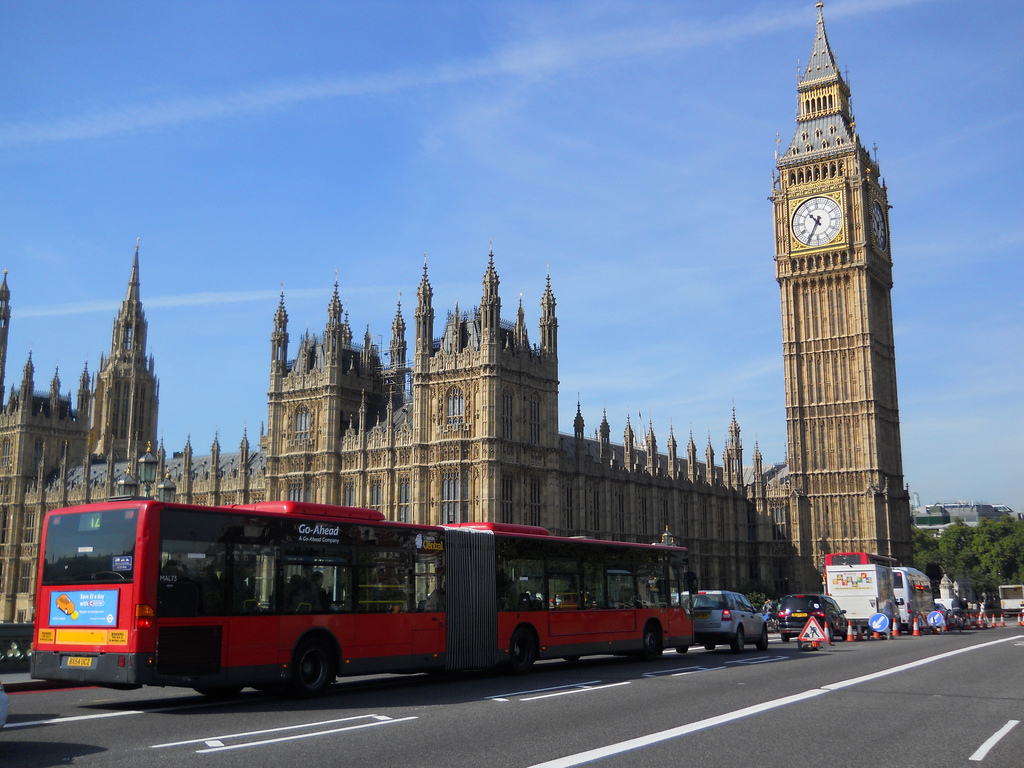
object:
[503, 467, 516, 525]
window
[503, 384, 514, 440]
window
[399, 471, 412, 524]
window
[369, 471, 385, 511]
window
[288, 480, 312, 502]
window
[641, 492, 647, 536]
window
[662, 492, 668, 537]
window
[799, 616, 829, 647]
sign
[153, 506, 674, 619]
window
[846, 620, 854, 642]
pylon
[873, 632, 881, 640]
pylon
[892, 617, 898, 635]
pylon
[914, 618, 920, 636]
pylon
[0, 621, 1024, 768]
road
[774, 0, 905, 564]
big ben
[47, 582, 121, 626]
advertising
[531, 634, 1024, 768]
line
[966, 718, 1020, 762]
line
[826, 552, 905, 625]
truck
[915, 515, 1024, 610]
tree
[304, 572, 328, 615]
passenger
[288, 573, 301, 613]
passenger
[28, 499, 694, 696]
bus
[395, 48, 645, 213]
white clouds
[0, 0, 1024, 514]
blue sky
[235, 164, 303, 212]
sky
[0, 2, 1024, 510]
clouds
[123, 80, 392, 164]
clouds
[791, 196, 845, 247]
clock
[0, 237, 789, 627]
building